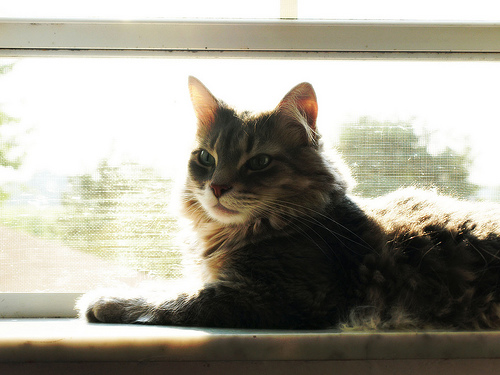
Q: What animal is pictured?
A: Cat.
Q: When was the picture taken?
A: Daytime.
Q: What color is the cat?
A: Brown.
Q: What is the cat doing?
A: Laying.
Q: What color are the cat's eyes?
A: Green.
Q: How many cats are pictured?
A: One.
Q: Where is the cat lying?
A: In the sunlight.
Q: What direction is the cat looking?
A: To the left.